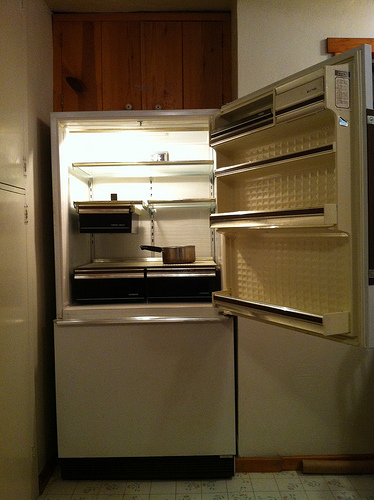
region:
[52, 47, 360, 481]
refrigerator and freezer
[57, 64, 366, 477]
empty refrigerator with the door wide open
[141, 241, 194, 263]
metal sauce pan in the refrigerator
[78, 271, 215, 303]
two vegetable crisping drawers in the refrigeratior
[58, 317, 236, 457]
bottom mount freezer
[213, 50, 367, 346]
open refrigerator door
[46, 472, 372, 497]
white vinyl flooring with floral pattern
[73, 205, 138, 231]
meat and dairy drawer in the refrigerator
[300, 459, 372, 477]
brown cardboard tube on the floor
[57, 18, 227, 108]
brown wood cabinets above the refrigerator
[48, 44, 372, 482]
a white refrigerator freezer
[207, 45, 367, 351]
an open refrigerator door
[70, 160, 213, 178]
a glass refrigerator shelf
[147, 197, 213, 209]
a glass refrigerator shelf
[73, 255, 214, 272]
a glass refrigerator shelf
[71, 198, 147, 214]
a glass refrigerator shelf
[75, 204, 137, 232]
a black refrigerator drawer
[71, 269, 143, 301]
a black refrigerator drawer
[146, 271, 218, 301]
a black refrigerator drawer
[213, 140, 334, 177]
a refrigerator door shelf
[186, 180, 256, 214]
refrigerator door is open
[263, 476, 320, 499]
flowers on the flooring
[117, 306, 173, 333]
handle on the freezer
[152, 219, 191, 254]
pot in the refrigerator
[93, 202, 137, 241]
drawer on the shelf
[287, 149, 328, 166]
shelves in the door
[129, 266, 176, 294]
two drawers under to pot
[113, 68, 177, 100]
cabinets above the refrigerator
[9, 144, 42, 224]
hinges on the doors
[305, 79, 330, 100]
BUTTER written on the door of compartment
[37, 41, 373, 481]
an open, white refrigerator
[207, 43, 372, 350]
open door of the refrigerator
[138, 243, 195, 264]
metal pot in the refrigerator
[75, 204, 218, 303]
black drawers inside of the refrigerator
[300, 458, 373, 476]
cardboard tube on the floor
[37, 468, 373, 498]
tiles on floor with floral pattern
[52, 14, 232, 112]
wooden cabinets above refrigerator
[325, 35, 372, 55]
wooden trim to the right of refrigerator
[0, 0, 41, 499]
white cabinets to the left of the refrigerator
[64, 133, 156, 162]
bright light in the refrigerator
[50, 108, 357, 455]
white fridge is open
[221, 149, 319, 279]
yellow wall on shelves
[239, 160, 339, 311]
fridge shelves are empty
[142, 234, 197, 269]
steel pot inside fridge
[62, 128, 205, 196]
white light shines in fridge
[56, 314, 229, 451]
white freezer below fridge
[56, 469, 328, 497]
white and floral tiled floor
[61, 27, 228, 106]
brown and knotty wooden doors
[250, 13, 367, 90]
white wall behind fridge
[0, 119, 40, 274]
white cabinet left of fridge